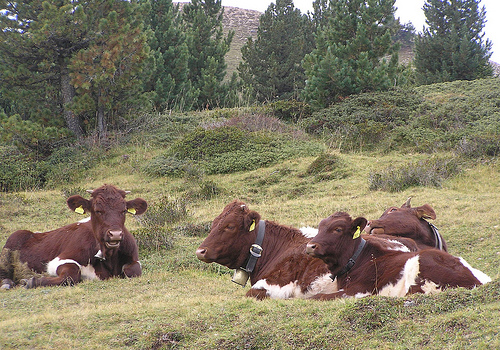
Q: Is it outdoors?
A: Yes, it is outdoors.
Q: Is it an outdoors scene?
A: Yes, it is outdoors.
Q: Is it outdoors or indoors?
A: It is outdoors.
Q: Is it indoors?
A: No, it is outdoors.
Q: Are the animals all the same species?
A: Yes, all the animals are cows.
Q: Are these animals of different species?
A: No, all the animals are cows.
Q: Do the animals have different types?
A: No, all the animals are cows.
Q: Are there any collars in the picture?
A: Yes, there is a collar.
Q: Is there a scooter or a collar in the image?
A: Yes, there is a collar.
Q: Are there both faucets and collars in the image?
A: No, there is a collar but no faucets.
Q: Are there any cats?
A: No, there are no cats.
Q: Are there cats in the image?
A: No, there are no cats.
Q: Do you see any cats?
A: No, there are no cats.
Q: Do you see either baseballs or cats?
A: No, there are no cats or baseballs.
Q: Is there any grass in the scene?
A: Yes, there is grass.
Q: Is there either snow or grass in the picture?
A: Yes, there is grass.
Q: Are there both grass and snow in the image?
A: No, there is grass but no snow.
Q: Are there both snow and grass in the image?
A: No, there is grass but no snow.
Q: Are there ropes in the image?
A: No, there are no ropes.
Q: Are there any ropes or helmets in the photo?
A: No, there are no ropes or helmets.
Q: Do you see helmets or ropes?
A: No, there are no ropes or helmets.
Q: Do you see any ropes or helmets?
A: No, there are no ropes or helmets.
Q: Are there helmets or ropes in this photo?
A: No, there are no ropes or helmets.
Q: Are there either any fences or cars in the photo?
A: No, there are no fences or cars.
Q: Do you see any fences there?
A: No, there are no fences.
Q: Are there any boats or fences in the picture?
A: No, there are no fences or boats.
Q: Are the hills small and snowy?
A: No, the hills are small but grassy.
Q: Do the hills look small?
A: Yes, the hills are small.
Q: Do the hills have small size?
A: Yes, the hills are small.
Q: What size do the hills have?
A: The hills have small size.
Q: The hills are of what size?
A: The hills are small.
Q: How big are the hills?
A: The hills are small.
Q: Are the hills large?
A: No, the hills are small.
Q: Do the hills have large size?
A: No, the hills are small.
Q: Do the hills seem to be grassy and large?
A: No, the hills are grassy but small.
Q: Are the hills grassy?
A: Yes, the hills are grassy.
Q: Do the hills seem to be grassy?
A: Yes, the hills are grassy.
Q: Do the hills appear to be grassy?
A: Yes, the hills are grassy.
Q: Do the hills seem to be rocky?
A: No, the hills are grassy.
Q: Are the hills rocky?
A: No, the hills are grassy.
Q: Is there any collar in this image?
A: Yes, there is a collar.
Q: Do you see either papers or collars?
A: Yes, there is a collar.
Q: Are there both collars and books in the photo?
A: No, there is a collar but no books.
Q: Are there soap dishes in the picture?
A: No, there are no soap dishes.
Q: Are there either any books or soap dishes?
A: No, there are no soap dishes or books.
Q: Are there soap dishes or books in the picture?
A: No, there are no soap dishes or books.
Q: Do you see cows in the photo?
A: Yes, there is a cow.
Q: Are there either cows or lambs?
A: Yes, there is a cow.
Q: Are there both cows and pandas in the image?
A: No, there is a cow but no pandas.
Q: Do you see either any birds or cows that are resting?
A: Yes, the cow is resting.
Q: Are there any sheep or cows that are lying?
A: Yes, the cow is lying.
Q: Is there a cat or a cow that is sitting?
A: Yes, the cow is sitting.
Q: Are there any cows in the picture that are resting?
A: Yes, there is a cow that is resting.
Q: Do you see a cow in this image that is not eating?
A: Yes, there is a cow that is resting .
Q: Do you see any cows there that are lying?
A: Yes, there is a cow that is lying.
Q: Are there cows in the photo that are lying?
A: Yes, there is a cow that is lying.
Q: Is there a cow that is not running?
A: Yes, there is a cow that is lying.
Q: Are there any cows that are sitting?
A: Yes, there is a cow that is sitting.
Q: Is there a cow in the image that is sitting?
A: Yes, there is a cow that is sitting.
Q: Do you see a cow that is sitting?
A: Yes, there is a cow that is sitting.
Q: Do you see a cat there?
A: No, there are no cats.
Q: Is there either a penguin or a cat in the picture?
A: No, there are no cats or penguins.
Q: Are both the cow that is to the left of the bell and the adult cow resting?
A: Yes, both the cow and the cow are resting.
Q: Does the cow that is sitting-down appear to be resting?
A: Yes, the cow is resting.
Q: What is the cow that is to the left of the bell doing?
A: The cow is resting.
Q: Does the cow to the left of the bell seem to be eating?
A: No, the cow is resting.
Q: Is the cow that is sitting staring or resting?
A: The cow is resting.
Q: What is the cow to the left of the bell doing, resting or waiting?
A: The cow is resting.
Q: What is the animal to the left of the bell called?
A: The animal is a cow.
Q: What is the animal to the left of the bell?
A: The animal is a cow.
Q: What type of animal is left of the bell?
A: The animal is a cow.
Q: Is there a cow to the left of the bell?
A: Yes, there is a cow to the left of the bell.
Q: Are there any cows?
A: Yes, there is a cow.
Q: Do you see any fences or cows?
A: Yes, there is a cow.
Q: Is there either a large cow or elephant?
A: Yes, there is a large cow.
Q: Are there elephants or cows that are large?
A: Yes, the cow is large.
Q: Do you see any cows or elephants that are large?
A: Yes, the cow is large.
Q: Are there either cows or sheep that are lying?
A: Yes, the cow is lying.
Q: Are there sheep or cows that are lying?
A: Yes, the cow is lying.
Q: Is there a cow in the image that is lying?
A: Yes, there is a cow that is lying.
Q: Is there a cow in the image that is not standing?
A: Yes, there is a cow that is lying.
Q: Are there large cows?
A: Yes, there is a large cow.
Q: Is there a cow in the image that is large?
A: Yes, there is a cow that is large.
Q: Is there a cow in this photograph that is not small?
A: Yes, there is a large cow.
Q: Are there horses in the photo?
A: No, there are no horses.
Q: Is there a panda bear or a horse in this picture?
A: No, there are no horses or panda bears.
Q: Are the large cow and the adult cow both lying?
A: Yes, both the cow and the cow are lying.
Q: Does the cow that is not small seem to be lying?
A: Yes, the cow is lying.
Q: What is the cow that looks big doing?
A: The cow is lying.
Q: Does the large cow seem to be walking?
A: No, the cow is lying.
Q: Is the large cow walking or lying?
A: The cow is lying.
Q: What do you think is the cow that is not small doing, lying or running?
A: The cow is lying.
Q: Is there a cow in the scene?
A: Yes, there is a cow.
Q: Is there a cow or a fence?
A: Yes, there is a cow.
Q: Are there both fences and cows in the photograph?
A: No, there is a cow but no fences.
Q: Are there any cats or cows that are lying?
A: Yes, the cow is lying.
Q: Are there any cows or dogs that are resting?
A: Yes, the cow is resting.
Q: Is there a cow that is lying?
A: Yes, there is a cow that is lying.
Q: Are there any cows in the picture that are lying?
A: Yes, there is a cow that is lying.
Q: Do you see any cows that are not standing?
A: Yes, there is a cow that is lying .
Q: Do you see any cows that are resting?
A: Yes, there is a cow that is resting.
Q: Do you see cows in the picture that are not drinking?
A: Yes, there is a cow that is resting .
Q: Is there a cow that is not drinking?
A: Yes, there is a cow that is resting.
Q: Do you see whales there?
A: No, there are no whales.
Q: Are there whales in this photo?
A: No, there are no whales.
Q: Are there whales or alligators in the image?
A: No, there are no whales or alligators.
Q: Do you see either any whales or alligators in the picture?
A: No, there are no whales or alligators.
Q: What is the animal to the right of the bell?
A: The animal is a cow.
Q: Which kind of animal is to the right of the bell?
A: The animal is a cow.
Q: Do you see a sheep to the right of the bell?
A: No, there is a cow to the right of the bell.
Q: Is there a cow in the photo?
A: Yes, there is a cow.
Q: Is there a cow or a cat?
A: Yes, there is a cow.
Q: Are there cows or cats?
A: Yes, there is a cow.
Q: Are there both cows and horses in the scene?
A: No, there is a cow but no horses.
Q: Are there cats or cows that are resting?
A: Yes, the cow is resting.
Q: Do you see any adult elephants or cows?
A: Yes, there is an adult cow.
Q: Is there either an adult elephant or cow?
A: Yes, there is an adult cow.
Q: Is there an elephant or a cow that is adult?
A: Yes, the cow is adult.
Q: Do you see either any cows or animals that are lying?
A: Yes, the cow is lying.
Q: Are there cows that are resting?
A: Yes, there is a cow that is resting.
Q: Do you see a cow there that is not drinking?
A: Yes, there is a cow that is resting .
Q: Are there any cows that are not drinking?
A: Yes, there is a cow that is resting.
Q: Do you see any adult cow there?
A: Yes, there is an adult cow.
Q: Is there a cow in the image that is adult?
A: Yes, there is a cow that is adult.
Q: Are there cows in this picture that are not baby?
A: Yes, there is a adult cow.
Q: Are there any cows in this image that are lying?
A: Yes, there is a cow that is lying.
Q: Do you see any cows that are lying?
A: Yes, there is a cow that is lying.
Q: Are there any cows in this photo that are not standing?
A: Yes, there is a cow that is lying.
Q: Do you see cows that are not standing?
A: Yes, there is a cow that is lying .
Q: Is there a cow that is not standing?
A: Yes, there is a cow that is lying.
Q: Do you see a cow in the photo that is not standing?
A: Yes, there is a cow that is lying .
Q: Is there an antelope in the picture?
A: No, there are no antelopes.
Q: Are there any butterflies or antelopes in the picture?
A: No, there are no antelopes or butterflies.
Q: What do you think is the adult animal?
A: The animal is a cow.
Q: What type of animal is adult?
A: The animal is a cow.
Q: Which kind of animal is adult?
A: The animal is a cow.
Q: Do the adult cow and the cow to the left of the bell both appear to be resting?
A: Yes, both the cow and the cow are resting.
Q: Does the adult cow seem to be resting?
A: Yes, the cow is resting.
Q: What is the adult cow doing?
A: The cow is resting.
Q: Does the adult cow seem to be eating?
A: No, the cow is resting.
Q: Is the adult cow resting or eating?
A: The cow is resting.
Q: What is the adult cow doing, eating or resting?
A: The cow is resting.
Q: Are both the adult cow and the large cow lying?
A: Yes, both the cow and the cow are lying.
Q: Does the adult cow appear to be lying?
A: Yes, the cow is lying.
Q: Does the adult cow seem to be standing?
A: No, the cow is lying.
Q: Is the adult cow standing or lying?
A: The cow is lying.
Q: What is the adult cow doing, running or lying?
A: The cow is lying.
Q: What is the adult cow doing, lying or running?
A: The cow is lying.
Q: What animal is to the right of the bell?
A: The animal is a cow.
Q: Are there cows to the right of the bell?
A: Yes, there is a cow to the right of the bell.